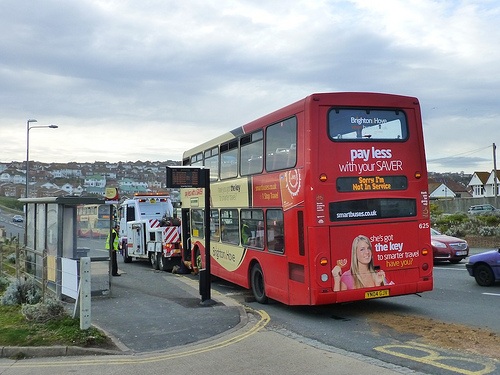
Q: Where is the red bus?
A: On the road.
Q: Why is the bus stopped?
A: To get repaired.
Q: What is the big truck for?
A: To tow the bus.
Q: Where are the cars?
A: On the road.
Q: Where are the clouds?
A: In the sky.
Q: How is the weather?
A: Cloudy.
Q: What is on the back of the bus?
A: A woman.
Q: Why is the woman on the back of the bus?
A: Advertising.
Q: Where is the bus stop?
A: On the sidewalk.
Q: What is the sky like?
A: Cloudy.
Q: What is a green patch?
A: Grass.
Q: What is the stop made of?
A: Glass.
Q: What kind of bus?
A: Double decker.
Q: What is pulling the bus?
A: Tow truck.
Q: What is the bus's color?
A: Red.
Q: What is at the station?
A: Shelter.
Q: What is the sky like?
A: Cloudy.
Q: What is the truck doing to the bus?
A: Towing.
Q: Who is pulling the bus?
A: Truck.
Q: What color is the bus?
A: Red.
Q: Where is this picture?
A: Bus stop.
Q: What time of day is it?
A: Evening.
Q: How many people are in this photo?
A: One.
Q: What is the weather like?
A: Cloudy.